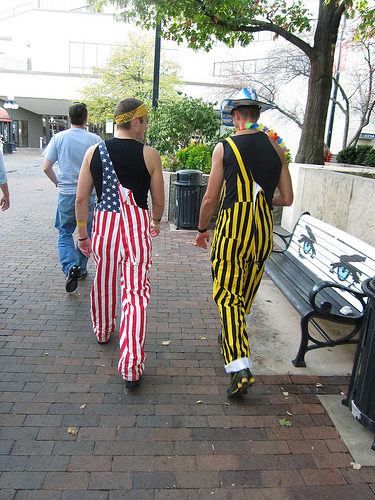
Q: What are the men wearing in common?
A: Black shirts.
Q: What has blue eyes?
A: Wooden bench on walkway.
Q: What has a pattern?
A: Yellow and black striped ovrealls.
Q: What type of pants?
A: Man wearing blue jeans.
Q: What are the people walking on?
A: Brick pathway.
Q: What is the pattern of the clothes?
A: Yellow and black overalls.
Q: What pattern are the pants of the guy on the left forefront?
A: Stars and stripes.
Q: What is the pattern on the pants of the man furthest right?
A: Yellow and black stripes.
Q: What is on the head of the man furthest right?
A: A hat.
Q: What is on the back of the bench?
A: Eyes.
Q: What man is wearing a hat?
A: The one furthest right.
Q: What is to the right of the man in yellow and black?
A: A bench.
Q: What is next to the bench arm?
A: A trash can.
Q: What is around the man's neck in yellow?
A: A lei.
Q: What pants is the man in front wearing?
A: Jeans.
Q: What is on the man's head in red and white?
A: A headband.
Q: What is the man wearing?
A: Overalls.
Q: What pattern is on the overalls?
A: The american flag.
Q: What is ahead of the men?
A: A garbage can.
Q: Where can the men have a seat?
A: On the bench.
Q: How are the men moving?
A: The men are walking.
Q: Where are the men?
A: On a sidewalk.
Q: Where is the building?
A: Ahead of the men.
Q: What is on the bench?
A: A pair of eyes.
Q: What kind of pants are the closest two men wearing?
A: Overalls.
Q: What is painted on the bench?
A: Eyes.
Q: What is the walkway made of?
A: Brick.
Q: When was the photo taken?
A: Daytime.